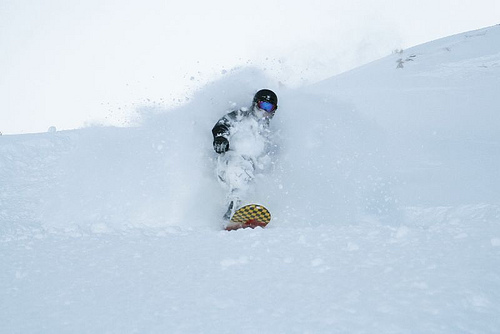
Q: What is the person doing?
A: Snowboarding.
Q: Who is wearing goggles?
A: Snowboarder.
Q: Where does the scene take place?
A: On ski slope.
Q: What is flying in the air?
A: Snow.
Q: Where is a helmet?
A: On person's head.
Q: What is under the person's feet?
A: Snowboard.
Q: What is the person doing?
A: Snowboarding.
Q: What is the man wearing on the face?
A: Goggles.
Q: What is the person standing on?
A: Snowboard.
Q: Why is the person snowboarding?
A: Because it snowed.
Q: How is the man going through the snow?
A: On a snowboard.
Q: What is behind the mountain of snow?
A: Cloudy sky.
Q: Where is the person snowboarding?
A: On a hill.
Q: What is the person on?
A: Snowboard.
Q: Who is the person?
A: Snowboarder.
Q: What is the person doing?
A: Snowboarding.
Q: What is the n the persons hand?
A: A glove.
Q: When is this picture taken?
A: Winter.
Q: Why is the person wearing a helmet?
A: Safety.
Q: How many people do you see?
A: One.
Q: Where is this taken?
A: A slope.